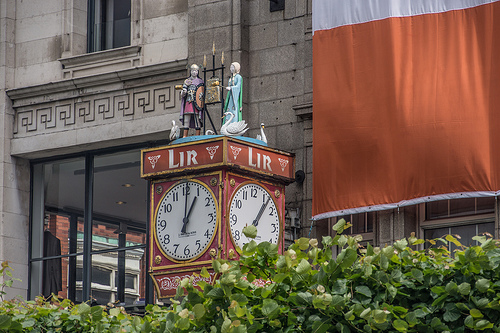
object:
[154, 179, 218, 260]
clock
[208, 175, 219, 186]
tower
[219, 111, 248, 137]
swan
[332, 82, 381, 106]
jacket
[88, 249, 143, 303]
window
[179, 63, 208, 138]
statue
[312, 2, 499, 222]
flag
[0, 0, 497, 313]
building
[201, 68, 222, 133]
glockenspiel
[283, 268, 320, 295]
leaves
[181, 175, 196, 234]
hand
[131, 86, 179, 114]
design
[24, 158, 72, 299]
doorway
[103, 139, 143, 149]
frame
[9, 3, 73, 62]
wall